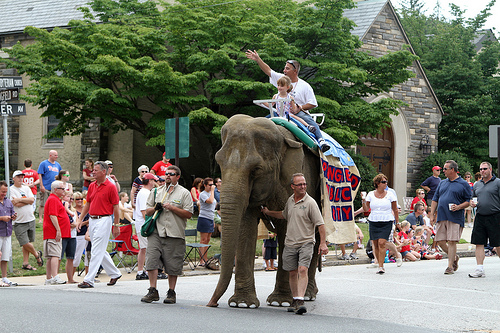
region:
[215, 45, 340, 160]
child and adult on an elephant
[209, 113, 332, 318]
elephant and trainer are walking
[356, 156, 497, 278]
woman and two men are walking behind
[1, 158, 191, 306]
group of people gathered to watch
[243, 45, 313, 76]
man is waving to the crowd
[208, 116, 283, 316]
the elephant is on the road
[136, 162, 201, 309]
the other trainer is next to the elephant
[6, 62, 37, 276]
man is leaning against the pole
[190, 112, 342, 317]
people are standing behind the elephant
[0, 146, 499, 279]
lots of people have gathered on this street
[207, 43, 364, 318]
a guy and a girl riding elephant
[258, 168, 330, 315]
a person guiding the elephant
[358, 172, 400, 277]
a person wearing white blouse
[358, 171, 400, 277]
a person wearing shirt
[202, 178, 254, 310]
a trunk of an elephant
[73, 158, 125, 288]
a person wearing white pants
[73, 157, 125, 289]
a person wearing red shirt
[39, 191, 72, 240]
a guy wearing a red shirt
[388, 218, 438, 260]
kids sitting on the curb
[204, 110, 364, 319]
an elephant walking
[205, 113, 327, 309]
an elephant in the street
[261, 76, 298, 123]
girl riding the elephant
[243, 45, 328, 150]
man waving from the top of the elephant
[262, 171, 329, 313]
man standing and holding on to the elephant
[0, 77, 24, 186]
black and white street signs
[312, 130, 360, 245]
sign on the back of the elephant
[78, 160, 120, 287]
man in red collared shirt and white pants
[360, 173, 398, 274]
woman behind the elephant wearing a white shirt and black shorts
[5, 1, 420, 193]
a tree in front of the building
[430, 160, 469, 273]
man in blue shirt and khaki shorts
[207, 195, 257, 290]
part of a trunk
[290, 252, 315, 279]
par tof a knee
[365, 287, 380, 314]
part of a line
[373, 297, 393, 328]
part of a floor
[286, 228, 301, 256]
part of a top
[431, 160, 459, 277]
a person wearing a blue shirt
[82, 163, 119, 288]
a man wearing a red shirt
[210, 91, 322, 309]
an elephant walking on the street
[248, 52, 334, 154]
two people sitting on an elephant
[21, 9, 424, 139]
a large tree in the background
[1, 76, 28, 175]
a street sign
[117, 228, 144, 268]
a red chair on the ground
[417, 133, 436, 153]
a light on the building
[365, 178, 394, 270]
a woman wearing a white shirt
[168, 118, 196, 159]
the back of a sign